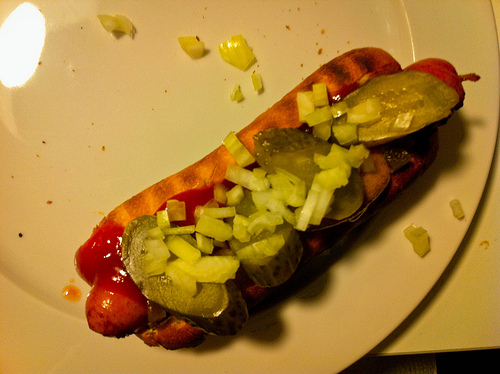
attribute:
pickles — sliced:
[88, 177, 320, 359]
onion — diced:
[196, 159, 363, 260]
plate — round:
[29, 11, 479, 372]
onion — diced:
[205, 208, 241, 232]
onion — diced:
[168, 232, 205, 264]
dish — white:
[2, 0, 497, 370]